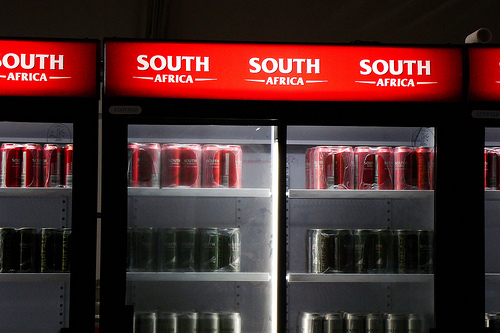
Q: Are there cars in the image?
A: No, there are no cars.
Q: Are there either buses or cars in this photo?
A: No, there are no cars or buses.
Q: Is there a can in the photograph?
A: Yes, there is a can.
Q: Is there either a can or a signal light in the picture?
A: Yes, there is a can.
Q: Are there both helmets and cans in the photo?
A: No, there is a can but no helmets.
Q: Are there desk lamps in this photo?
A: No, there are no desk lamps.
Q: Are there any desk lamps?
A: No, there are no desk lamps.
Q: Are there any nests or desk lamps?
A: No, there are no desk lamps or nests.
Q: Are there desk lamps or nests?
A: No, there are no desk lamps or nests.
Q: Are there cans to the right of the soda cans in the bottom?
A: Yes, there is a can to the right of the soda cans.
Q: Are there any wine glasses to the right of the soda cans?
A: No, there is a can to the right of the soda cans.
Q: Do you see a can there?
A: Yes, there is a can.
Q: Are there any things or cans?
A: Yes, there is a can.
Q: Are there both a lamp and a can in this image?
A: No, there is a can but no lamps.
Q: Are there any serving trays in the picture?
A: No, there are no serving trays.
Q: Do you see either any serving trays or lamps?
A: No, there are no serving trays or lamps.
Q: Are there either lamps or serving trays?
A: No, there are no serving trays or lamps.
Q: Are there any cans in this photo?
A: Yes, there is a can.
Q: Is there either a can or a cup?
A: Yes, there is a can.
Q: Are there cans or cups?
A: Yes, there is a can.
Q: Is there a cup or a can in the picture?
A: Yes, there is a can.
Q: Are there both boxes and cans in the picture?
A: No, there is a can but no boxes.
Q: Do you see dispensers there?
A: No, there are no dispensers.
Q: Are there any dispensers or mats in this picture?
A: No, there are no dispensers or mats.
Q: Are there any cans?
A: Yes, there is a can.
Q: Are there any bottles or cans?
A: Yes, there is a can.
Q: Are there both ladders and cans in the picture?
A: No, there is a can but no ladders.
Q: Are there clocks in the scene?
A: No, there are no clocks.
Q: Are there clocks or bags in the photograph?
A: No, there are no clocks or bags.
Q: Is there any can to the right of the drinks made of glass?
A: Yes, there is a can to the right of the drinks.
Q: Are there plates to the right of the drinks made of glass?
A: No, there is a can to the right of the drinks.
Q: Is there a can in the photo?
A: Yes, there is a can.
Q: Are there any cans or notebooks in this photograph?
A: Yes, there is a can.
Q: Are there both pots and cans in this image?
A: No, there is a can but no pots.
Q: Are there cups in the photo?
A: No, there are no cups.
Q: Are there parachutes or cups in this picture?
A: No, there are no cups or parachutes.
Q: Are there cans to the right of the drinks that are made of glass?
A: Yes, there is a can to the right of the drinks.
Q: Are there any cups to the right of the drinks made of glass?
A: No, there is a can to the right of the drinks.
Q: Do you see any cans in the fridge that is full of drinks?
A: Yes, there is a can in the fridge.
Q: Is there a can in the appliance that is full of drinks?
A: Yes, there is a can in the fridge.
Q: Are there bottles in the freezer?
A: No, there is a can in the freezer.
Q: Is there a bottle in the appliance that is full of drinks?
A: No, there is a can in the freezer.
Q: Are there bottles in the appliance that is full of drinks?
A: No, there is a can in the freezer.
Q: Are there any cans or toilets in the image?
A: Yes, there is a can.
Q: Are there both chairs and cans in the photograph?
A: No, there is a can but no chairs.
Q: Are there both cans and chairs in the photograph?
A: No, there is a can but no chairs.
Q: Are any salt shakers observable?
A: No, there are no salt shakers.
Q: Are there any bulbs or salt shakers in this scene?
A: No, there are no salt shakers or bulbs.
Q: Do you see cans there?
A: Yes, there is a can.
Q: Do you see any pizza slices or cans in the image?
A: Yes, there is a can.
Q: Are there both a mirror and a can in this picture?
A: No, there is a can but no mirrors.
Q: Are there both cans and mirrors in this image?
A: No, there is a can but no mirrors.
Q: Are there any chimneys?
A: No, there are no chimneys.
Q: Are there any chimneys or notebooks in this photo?
A: No, there are no chimneys or notebooks.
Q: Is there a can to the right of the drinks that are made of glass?
A: Yes, there is a can to the right of the drinks.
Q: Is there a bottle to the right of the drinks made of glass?
A: No, there is a can to the right of the drinks.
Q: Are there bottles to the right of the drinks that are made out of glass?
A: No, there is a can to the right of the drinks.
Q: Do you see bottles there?
A: No, there are no bottles.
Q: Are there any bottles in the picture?
A: No, there are no bottles.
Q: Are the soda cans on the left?
A: Yes, the soda cans are on the left of the image.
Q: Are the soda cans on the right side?
A: No, the soda cans are on the left of the image.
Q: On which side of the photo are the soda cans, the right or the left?
A: The soda cans are on the left of the image.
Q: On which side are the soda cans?
A: The soda cans are on the left of the image.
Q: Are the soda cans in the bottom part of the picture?
A: Yes, the soda cans are in the bottom of the image.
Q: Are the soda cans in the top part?
A: No, the soda cans are in the bottom of the image.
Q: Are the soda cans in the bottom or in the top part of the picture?
A: The soda cans are in the bottom of the image.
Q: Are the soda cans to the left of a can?
A: Yes, the soda cans are to the left of a can.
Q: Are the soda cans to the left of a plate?
A: No, the soda cans are to the left of a can.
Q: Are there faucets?
A: No, there are no faucets.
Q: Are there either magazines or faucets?
A: No, there are no faucets or magazines.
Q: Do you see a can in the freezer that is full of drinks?
A: Yes, there are cans in the fridge.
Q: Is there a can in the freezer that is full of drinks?
A: Yes, there are cans in the fridge.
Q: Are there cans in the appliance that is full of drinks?
A: Yes, there are cans in the fridge.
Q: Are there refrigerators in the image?
A: Yes, there is a refrigerator.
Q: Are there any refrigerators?
A: Yes, there is a refrigerator.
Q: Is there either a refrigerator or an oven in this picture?
A: Yes, there is a refrigerator.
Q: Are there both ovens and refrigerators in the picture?
A: No, there is a refrigerator but no ovens.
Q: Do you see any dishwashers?
A: No, there are no dishwashers.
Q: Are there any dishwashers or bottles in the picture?
A: No, there are no dishwashers or bottles.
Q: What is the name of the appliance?
A: The appliance is a refrigerator.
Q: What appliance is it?
A: The appliance is a refrigerator.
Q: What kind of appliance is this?
A: This is a refrigerator.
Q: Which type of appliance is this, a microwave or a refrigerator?
A: This is a refrigerator.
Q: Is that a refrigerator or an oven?
A: That is a refrigerator.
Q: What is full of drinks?
A: The refrigerator is full of drinks.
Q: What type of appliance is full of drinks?
A: The appliance is a refrigerator.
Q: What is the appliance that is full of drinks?
A: The appliance is a refrigerator.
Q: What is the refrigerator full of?
A: The refrigerator is full of drinks.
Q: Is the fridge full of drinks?
A: Yes, the fridge is full of drinks.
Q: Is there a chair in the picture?
A: No, there are no chairs.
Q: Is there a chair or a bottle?
A: No, there are no chairs or bottles.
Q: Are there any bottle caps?
A: No, there are no bottle caps.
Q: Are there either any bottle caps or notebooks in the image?
A: No, there are no bottle caps or notebooks.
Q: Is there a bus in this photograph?
A: No, there are no buses.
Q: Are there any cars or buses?
A: No, there are no buses or cars.